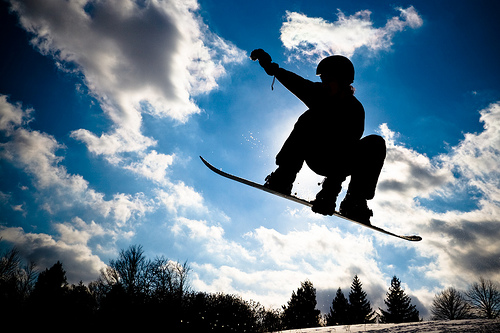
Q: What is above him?
A: Sky.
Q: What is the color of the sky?
A: Blue and white.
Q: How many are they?
A: 1.